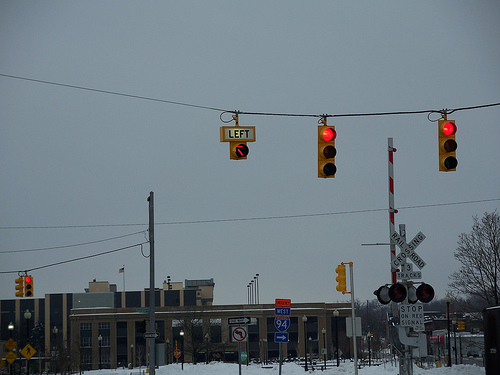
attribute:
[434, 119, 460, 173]
traffic light — red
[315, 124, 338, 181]
traffic light — red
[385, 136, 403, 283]
pole — white, red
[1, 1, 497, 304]
sky — white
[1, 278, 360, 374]
building — big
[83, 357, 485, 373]
snow — white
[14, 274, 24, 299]
traffic light — yellow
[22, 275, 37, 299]
stoplight — yellow, traffic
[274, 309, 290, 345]
sign — blue, white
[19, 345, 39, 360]
sign — yellow